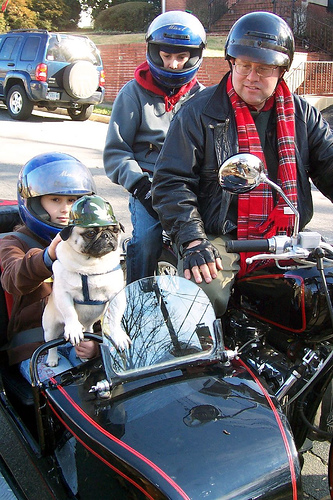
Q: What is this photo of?
A: People on bikes.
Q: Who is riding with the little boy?
A: A dog.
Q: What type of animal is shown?
A: Dog.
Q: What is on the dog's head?
A: Helmet.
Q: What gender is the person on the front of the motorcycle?
A: Male.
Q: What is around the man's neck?
A: Scarf.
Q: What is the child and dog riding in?
A: Cart.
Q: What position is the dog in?
A: Standing.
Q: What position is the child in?
A: Sitting.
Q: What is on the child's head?
A: Helmet.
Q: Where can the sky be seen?
A: Reflection in the window on the front of the cart.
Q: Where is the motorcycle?
A: Road.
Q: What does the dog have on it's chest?
A: A leash that goes on the abdomen.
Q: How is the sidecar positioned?
A: It is parallel to the motorcycle.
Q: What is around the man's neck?
A: A plaid scarf.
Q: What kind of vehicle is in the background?
A: An SUV.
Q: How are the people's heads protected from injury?
A: They are wearing helmets.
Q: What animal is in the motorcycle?
A: Dog.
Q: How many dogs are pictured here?
A: One.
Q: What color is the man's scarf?
A: Red.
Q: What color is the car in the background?
A: Blue.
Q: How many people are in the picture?
A: Three.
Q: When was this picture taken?
A: Daytime.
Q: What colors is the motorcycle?
A: Black and Red.